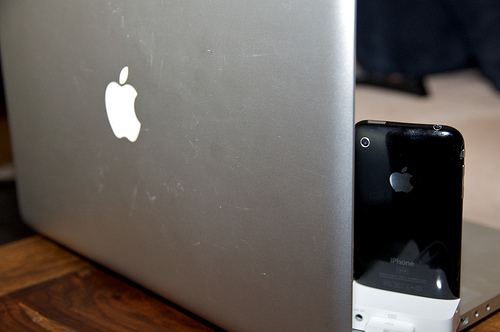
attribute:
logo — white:
[102, 65, 143, 143]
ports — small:
[461, 304, 491, 325]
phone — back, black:
[352, 120, 464, 300]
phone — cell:
[352, 122, 464, 329]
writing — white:
[389, 255, 416, 268]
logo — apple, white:
[94, 56, 148, 147]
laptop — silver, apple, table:
[1, 0, 498, 330]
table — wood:
[1, 220, 498, 327]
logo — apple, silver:
[83, 50, 144, 154]